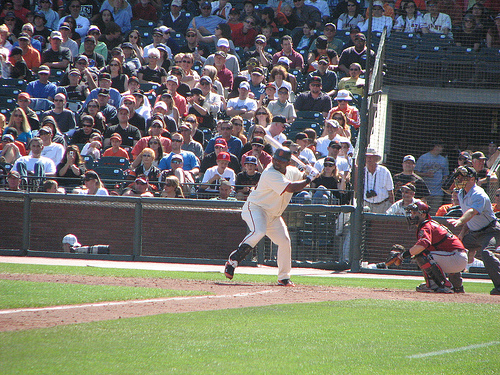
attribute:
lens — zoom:
[95, 245, 108, 256]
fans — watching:
[1, 1, 231, 173]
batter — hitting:
[220, 134, 322, 291]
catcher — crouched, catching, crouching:
[385, 198, 474, 299]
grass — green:
[264, 308, 378, 362]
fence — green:
[2, 187, 363, 275]